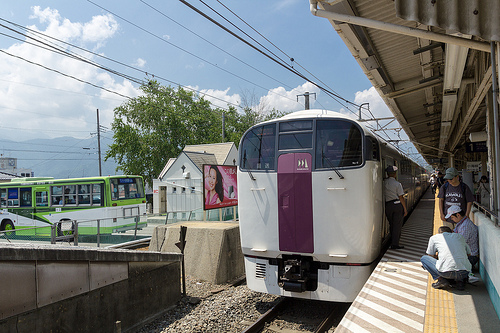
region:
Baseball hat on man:
[439, 165, 457, 181]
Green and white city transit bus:
[3, 168, 153, 250]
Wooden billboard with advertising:
[197, 156, 237, 213]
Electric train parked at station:
[235, 101, 424, 311]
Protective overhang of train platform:
[311, 10, 496, 174]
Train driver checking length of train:
[382, 162, 410, 253]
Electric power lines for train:
[5, 10, 430, 167]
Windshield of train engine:
[235, 116, 362, 172]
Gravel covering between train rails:
[130, 285, 272, 331]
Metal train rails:
[226, 302, 346, 329]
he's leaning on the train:
[376, 161, 415, 239]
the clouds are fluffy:
[27, 76, 59, 114]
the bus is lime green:
[95, 180, 115, 205]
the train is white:
[326, 190, 356, 225]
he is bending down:
[420, 220, 472, 292]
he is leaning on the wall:
[455, 217, 485, 252]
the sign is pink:
[220, 167, 235, 187]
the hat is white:
[440, 200, 465, 218]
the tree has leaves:
[142, 103, 178, 133]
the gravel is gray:
[194, 304, 230, 324]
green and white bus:
[7, 171, 144, 237]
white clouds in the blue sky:
[1, 4, 396, 169]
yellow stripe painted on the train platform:
[425, 184, 460, 331]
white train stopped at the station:
[235, 107, 380, 309]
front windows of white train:
[241, 121, 357, 168]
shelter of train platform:
[316, 0, 491, 167]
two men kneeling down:
[418, 207, 487, 287]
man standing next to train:
[382, 165, 408, 242]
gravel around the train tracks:
[149, 269, 347, 331]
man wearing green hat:
[434, 165, 470, 227]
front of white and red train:
[243, 110, 376, 307]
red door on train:
[272, 145, 322, 260]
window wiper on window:
[322, 148, 350, 188]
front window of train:
[320, 113, 357, 167]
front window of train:
[238, 129, 275, 166]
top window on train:
[275, 125, 315, 148]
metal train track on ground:
[248, 306, 279, 330]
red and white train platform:
[360, 265, 422, 331]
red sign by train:
[200, 166, 240, 207]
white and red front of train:
[232, 112, 371, 296]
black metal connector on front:
[275, 256, 311, 291]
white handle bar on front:
[325, 182, 348, 190]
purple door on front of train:
[277, 149, 312, 250]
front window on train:
[315, 118, 360, 165]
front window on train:
[242, 125, 277, 169]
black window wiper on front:
[317, 159, 345, 181]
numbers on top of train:
[278, 120, 311, 127]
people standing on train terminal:
[372, 170, 480, 293]